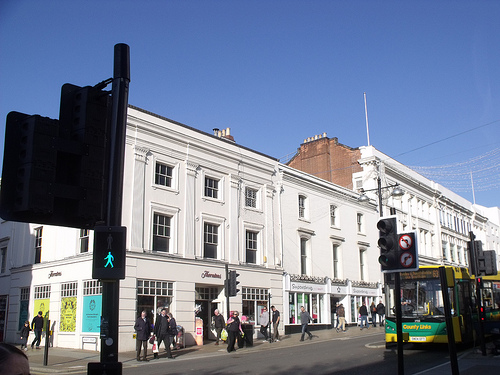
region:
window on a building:
[149, 157, 180, 187]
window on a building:
[200, 168, 225, 200]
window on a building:
[240, 182, 264, 209]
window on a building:
[147, 204, 179, 252]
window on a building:
[195, 218, 223, 261]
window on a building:
[242, 223, 262, 266]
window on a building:
[292, 193, 311, 222]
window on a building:
[297, 232, 311, 279]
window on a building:
[325, 200, 340, 232]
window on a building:
[332, 240, 343, 282]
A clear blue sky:
[236, 26, 281, 64]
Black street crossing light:
[97, 233, 122, 270]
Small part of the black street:
[286, 356, 306, 367]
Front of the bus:
[404, 272, 438, 340]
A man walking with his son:
[18, 310, 46, 349]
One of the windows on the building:
[202, 223, 222, 260]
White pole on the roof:
[359, 85, 375, 145]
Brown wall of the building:
[318, 151, 335, 168]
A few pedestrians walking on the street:
[328, 298, 382, 329]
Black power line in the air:
[424, 133, 460, 147]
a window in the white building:
[152, 160, 173, 186]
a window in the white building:
[202, 172, 224, 201]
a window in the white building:
[240, 182, 259, 208]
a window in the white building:
[148, 208, 174, 250]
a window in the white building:
[202, 216, 220, 261]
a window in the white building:
[244, 225, 262, 263]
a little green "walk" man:
[102, 248, 117, 269]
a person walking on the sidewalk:
[132, 313, 148, 357]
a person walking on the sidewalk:
[152, 305, 176, 355]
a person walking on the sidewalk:
[223, 309, 240, 348]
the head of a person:
[131, 305, 164, 320]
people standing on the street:
[130, 260, 242, 350]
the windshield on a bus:
[366, 240, 483, 350]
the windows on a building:
[134, 203, 230, 281]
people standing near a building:
[124, 290, 196, 358]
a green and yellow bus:
[353, 254, 498, 362]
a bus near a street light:
[370, 203, 479, 337]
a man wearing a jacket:
[287, 292, 335, 337]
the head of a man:
[289, 291, 321, 316]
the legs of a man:
[286, 317, 331, 348]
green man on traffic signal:
[91, 251, 125, 272]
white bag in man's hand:
[143, 328, 170, 354]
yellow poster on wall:
[49, 292, 82, 332]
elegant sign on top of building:
[197, 267, 236, 279]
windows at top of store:
[135, 276, 184, 288]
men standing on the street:
[136, 300, 188, 359]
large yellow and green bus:
[373, 258, 475, 345]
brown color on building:
[271, 125, 366, 190]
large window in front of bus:
[386, 281, 461, 325]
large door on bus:
[451, 272, 473, 337]